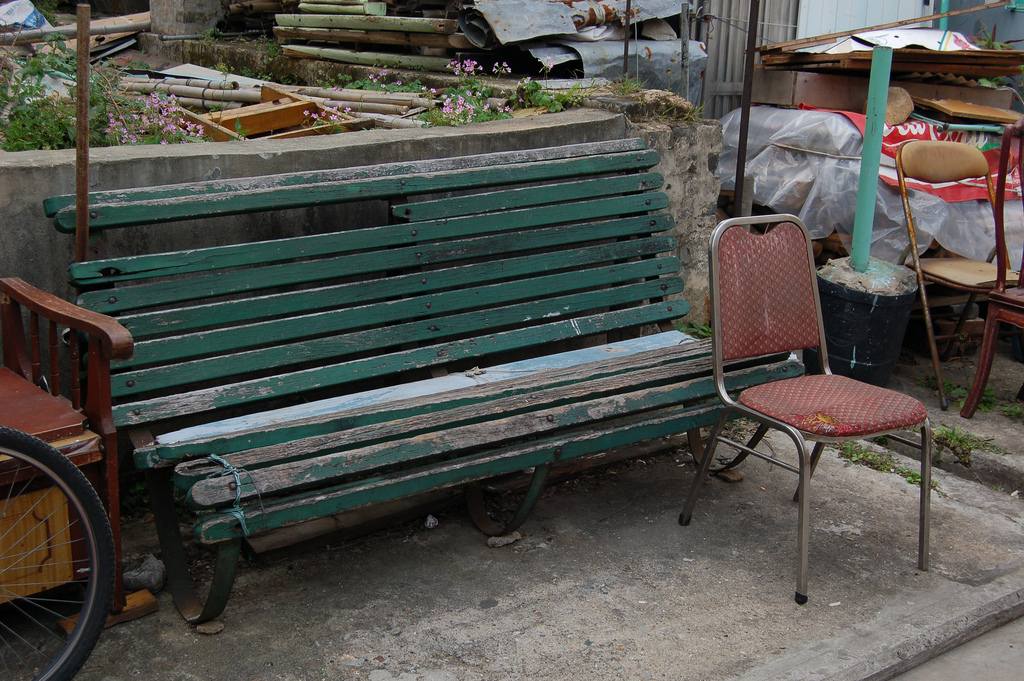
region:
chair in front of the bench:
[670, 198, 959, 601]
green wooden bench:
[38, 126, 816, 630]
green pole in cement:
[841, 41, 900, 270]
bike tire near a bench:
[5, 410, 120, 679]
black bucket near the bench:
[809, 253, 920, 381]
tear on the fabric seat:
[790, 407, 836, 434]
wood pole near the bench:
[69, 0, 98, 279]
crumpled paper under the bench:
[423, 508, 442, 537]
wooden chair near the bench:
[3, 265, 140, 617]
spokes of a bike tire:
[2, 452, 91, 678]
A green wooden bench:
[24, 131, 822, 637]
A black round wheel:
[0, 416, 130, 672]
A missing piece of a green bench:
[35, 159, 427, 286]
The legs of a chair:
[661, 418, 950, 615]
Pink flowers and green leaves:
[7, 39, 207, 157]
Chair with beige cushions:
[885, 128, 1016, 411]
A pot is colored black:
[804, 244, 923, 390]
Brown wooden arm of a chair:
[0, 260, 159, 621]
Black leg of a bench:
[138, 512, 247, 637]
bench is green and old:
[37, 135, 810, 625]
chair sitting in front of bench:
[43, 129, 947, 613]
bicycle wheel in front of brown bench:
[0, 265, 143, 678]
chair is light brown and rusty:
[890, 136, 1015, 419]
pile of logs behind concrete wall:
[2, 67, 635, 396]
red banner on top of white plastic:
[713, 102, 1023, 265]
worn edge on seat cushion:
[736, 367, 930, 435]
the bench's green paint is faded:
[43, 140, 796, 638]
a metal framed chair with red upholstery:
[672, 210, 939, 610]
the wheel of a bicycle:
[0, 412, 111, 678]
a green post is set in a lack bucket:
[812, 39, 926, 397]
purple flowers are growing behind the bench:
[82, 50, 529, 161]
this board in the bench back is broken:
[389, 166, 668, 230]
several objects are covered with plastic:
[699, 91, 1022, 313]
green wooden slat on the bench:
[77, 206, 673, 311]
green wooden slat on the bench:
[106, 229, 683, 335]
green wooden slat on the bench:
[90, 251, 685, 349]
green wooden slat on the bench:
[108, 296, 682, 427]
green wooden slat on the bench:
[58, 141, 660, 230]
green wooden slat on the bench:
[187, 359, 808, 496]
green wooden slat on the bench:
[194, 396, 760, 548]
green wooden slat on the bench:
[152, 334, 728, 472]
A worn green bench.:
[40, 136, 806, 626]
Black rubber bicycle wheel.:
[3, 422, 118, 679]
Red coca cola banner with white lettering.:
[798, 101, 1023, 207]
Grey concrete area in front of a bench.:
[2, 416, 1023, 679]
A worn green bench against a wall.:
[37, 136, 809, 627]